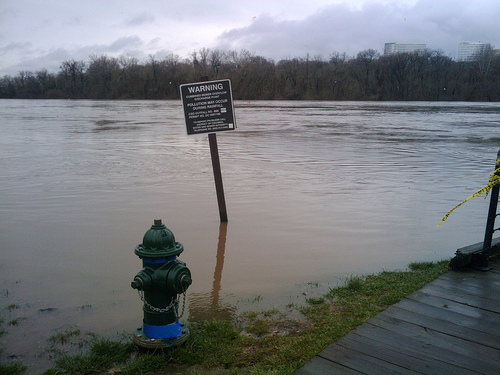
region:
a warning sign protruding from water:
[177, 74, 247, 251]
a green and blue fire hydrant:
[132, 225, 187, 338]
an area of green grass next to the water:
[202, 311, 239, 366]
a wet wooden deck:
[367, 311, 452, 371]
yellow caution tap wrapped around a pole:
[462, 163, 498, 267]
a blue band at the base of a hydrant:
[141, 319, 184, 337]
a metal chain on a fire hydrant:
[138, 294, 185, 317]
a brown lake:
[36, 117, 170, 211]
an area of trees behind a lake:
[265, 51, 497, 98]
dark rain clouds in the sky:
[238, 4, 406, 48]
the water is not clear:
[279, 139, 374, 224]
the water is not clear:
[276, 140, 399, 292]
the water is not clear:
[248, 110, 368, 312]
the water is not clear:
[272, 123, 347, 270]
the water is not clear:
[275, 162, 427, 370]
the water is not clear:
[301, 177, 350, 285]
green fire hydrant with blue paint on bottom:
[131, 207, 196, 354]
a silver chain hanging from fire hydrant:
[140, 292, 195, 314]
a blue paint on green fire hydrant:
[140, 319, 182, 340]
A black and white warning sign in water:
[178, 47, 263, 217]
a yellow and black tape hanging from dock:
[438, 155, 488, 222]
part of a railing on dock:
[458, 185, 499, 270]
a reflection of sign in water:
[202, 222, 257, 309]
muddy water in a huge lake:
[3, 101, 493, 296]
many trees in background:
[11, 42, 498, 104]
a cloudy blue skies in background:
[28, 2, 494, 57]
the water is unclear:
[62, 151, 168, 220]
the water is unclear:
[257, 140, 352, 225]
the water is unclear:
[292, 125, 394, 293]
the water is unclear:
[279, 165, 338, 315]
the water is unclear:
[266, 184, 371, 363]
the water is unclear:
[301, 183, 374, 318]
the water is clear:
[287, 148, 365, 243]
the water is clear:
[256, 122, 392, 304]